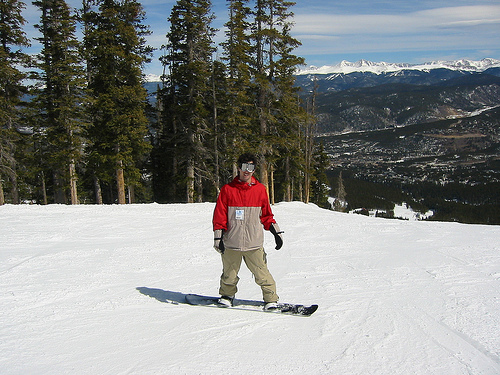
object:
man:
[216, 156, 284, 303]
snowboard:
[183, 292, 327, 315]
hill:
[0, 196, 500, 345]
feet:
[216, 295, 234, 308]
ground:
[11, 201, 495, 366]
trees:
[160, 0, 215, 200]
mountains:
[340, 54, 401, 70]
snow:
[326, 250, 378, 281]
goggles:
[240, 162, 256, 172]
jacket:
[211, 177, 275, 252]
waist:
[225, 221, 263, 231]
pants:
[217, 248, 280, 309]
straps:
[215, 296, 235, 308]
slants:
[349, 105, 487, 160]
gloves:
[269, 222, 285, 250]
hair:
[237, 152, 258, 169]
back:
[312, 4, 339, 32]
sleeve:
[212, 191, 228, 232]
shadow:
[132, 285, 181, 306]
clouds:
[368, 6, 413, 39]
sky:
[324, 51, 353, 61]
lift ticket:
[235, 208, 246, 220]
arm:
[259, 185, 277, 228]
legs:
[242, 250, 280, 304]